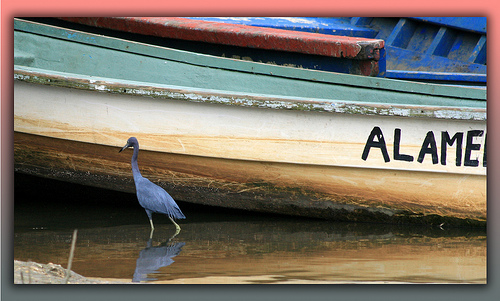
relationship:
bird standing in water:
[118, 137, 188, 230] [13, 229, 485, 287]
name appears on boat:
[363, 125, 490, 169] [54, 34, 498, 252]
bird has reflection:
[118, 137, 188, 230] [131, 229, 185, 282]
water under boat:
[193, 222, 478, 269] [13, 17, 487, 229]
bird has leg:
[118, 137, 188, 230] [166, 220, 182, 229]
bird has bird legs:
[118, 137, 188, 230] [144, 208, 156, 230]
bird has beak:
[118, 137, 188, 230] [117, 142, 135, 154]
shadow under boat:
[13, 171, 327, 232] [13, 17, 487, 229]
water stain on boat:
[161, 129, 279, 154] [100, 16, 496, 264]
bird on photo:
[118, 137, 188, 230] [15, 14, 489, 283]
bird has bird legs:
[118, 137, 188, 230] [138, 212, 190, 247]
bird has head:
[117, 134, 185, 241] [113, 129, 140, 155]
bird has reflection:
[118, 137, 188, 230] [123, 234, 201, 298]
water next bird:
[132, 251, 390, 274] [118, 137, 188, 230]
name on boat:
[360, 126, 488, 167] [4, 7, 487, 240]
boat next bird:
[13, 17, 487, 229] [118, 137, 188, 230]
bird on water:
[118, 137, 188, 230] [16, 162, 486, 284]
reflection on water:
[131, 229, 185, 282] [269, 245, 467, 269]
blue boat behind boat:
[14, 17, 488, 87] [33, 78, 492, 217]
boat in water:
[36, 28, 482, 217] [40, 209, 361, 264]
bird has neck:
[118, 137, 188, 230] [126, 145, 142, 172]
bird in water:
[118, 137, 188, 230] [11, 216, 486, 283]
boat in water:
[13, 17, 487, 229] [54, 110, 499, 272]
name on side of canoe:
[360, 126, 488, 167] [10, 17, 485, 222]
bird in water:
[118, 137, 188, 230] [9, 180, 490, 285]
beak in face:
[120, 142, 128, 153] [123, 136, 137, 150]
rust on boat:
[118, 17, 384, 75] [13, 17, 487, 229]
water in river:
[20, 240, 487, 282] [13, 164, 499, 288]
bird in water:
[118, 137, 188, 230] [16, 162, 486, 284]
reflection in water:
[131, 225, 178, 285] [16, 162, 486, 284]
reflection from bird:
[131, 225, 178, 285] [118, 137, 188, 230]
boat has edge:
[13, 17, 487, 229] [344, 14, 488, 84]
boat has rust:
[13, 17, 487, 229] [18, 112, 105, 157]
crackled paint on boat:
[185, 87, 269, 109] [4, 7, 487, 240]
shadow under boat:
[25, 206, 124, 234] [19, 34, 465, 232]